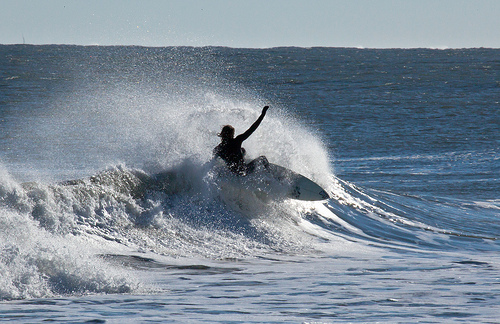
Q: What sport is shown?
A: Surfing.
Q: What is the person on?
A: Surfboard.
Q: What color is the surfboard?
A: White.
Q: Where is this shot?
A: Ocean.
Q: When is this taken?
A: Daytime.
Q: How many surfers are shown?
A: 1.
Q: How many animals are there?
A: 0.